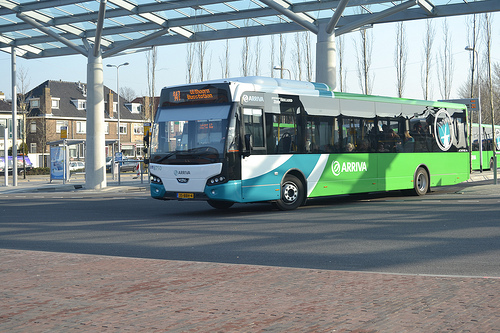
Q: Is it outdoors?
A: Yes, it is outdoors.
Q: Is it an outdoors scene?
A: Yes, it is outdoors.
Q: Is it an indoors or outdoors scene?
A: It is outdoors.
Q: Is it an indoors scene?
A: No, it is outdoors.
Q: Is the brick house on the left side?
A: Yes, the house is on the left of the image.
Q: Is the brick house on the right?
A: No, the house is on the left of the image.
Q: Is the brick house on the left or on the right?
A: The house is on the left of the image.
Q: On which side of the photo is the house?
A: The house is on the left of the image.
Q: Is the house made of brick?
A: Yes, the house is made of brick.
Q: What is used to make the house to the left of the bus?
A: The house is made of brick.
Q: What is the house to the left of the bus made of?
A: The house is made of brick.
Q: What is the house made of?
A: The house is made of brick.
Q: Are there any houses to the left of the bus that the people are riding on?
A: Yes, there is a house to the left of the bus.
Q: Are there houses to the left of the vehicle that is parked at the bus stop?
A: Yes, there is a house to the left of the bus.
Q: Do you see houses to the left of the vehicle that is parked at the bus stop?
A: Yes, there is a house to the left of the bus.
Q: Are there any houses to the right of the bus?
A: No, the house is to the left of the bus.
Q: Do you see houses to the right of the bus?
A: No, the house is to the left of the bus.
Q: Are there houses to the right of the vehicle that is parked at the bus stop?
A: No, the house is to the left of the bus.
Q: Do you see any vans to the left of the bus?
A: No, there is a house to the left of the bus.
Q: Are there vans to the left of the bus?
A: No, there is a house to the left of the bus.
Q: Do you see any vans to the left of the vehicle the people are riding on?
A: No, there is a house to the left of the bus.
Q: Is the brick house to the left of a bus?
A: Yes, the house is to the left of a bus.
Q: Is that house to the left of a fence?
A: No, the house is to the left of a bus.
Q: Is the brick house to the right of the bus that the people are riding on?
A: No, the house is to the left of the bus.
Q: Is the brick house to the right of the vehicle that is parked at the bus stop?
A: No, the house is to the left of the bus.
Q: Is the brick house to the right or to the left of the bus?
A: The house is to the left of the bus.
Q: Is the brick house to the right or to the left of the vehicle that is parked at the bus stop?
A: The house is to the left of the bus.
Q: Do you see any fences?
A: No, there are no fences.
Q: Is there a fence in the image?
A: No, there are no fences.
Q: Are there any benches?
A: No, there are no benches.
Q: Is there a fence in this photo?
A: No, there are no fences.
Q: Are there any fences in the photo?
A: No, there are no fences.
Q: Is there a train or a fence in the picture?
A: No, there are no fences or trains.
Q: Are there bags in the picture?
A: No, there are no bags.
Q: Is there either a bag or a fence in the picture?
A: No, there are no bags or fences.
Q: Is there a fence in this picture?
A: No, there are no fences.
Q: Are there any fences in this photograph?
A: No, there are no fences.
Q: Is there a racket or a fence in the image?
A: No, there are no fences or rackets.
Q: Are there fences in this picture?
A: No, there are no fences.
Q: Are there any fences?
A: No, there are no fences.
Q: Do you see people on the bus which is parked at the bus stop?
A: Yes, there are people on the bus.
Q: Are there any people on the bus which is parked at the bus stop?
A: Yes, there are people on the bus.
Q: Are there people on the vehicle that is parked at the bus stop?
A: Yes, there are people on the bus.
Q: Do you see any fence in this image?
A: No, there are no fences.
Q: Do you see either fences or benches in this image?
A: No, there are no fences or benches.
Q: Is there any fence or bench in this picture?
A: No, there are no fences or benches.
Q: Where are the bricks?
A: The bricks are on the sidewalk.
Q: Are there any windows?
A: Yes, there is a window.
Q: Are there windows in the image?
A: Yes, there is a window.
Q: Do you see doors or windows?
A: Yes, there is a window.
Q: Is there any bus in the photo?
A: Yes, there is a bus.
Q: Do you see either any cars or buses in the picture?
A: Yes, there is a bus.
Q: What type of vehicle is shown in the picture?
A: The vehicle is a bus.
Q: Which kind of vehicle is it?
A: The vehicle is a bus.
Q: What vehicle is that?
A: This is a bus.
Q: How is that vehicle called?
A: This is a bus.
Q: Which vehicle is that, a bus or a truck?
A: This is a bus.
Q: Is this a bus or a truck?
A: This is a bus.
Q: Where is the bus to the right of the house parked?
A: The bus is parked at the bus stop.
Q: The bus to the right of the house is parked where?
A: The bus is parked at the bus stop.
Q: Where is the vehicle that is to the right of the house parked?
A: The bus is parked at the bus stop.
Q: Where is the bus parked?
A: The bus is parked at the bus stop.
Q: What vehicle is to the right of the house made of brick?
A: The vehicle is a bus.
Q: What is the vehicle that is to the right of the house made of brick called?
A: The vehicle is a bus.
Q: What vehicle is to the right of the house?
A: The vehicle is a bus.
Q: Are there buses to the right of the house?
A: Yes, there is a bus to the right of the house.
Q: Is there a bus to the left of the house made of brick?
A: No, the bus is to the right of the house.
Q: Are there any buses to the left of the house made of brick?
A: No, the bus is to the right of the house.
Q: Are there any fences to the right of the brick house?
A: No, there is a bus to the right of the house.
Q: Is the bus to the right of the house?
A: Yes, the bus is to the right of the house.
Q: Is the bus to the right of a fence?
A: No, the bus is to the right of the house.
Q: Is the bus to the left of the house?
A: No, the bus is to the right of the house.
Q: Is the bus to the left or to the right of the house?
A: The bus is to the right of the house.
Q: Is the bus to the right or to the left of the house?
A: The bus is to the right of the house.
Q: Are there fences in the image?
A: No, there are no fences.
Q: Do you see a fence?
A: No, there are no fences.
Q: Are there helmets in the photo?
A: No, there are no helmets.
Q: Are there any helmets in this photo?
A: No, there are no helmets.